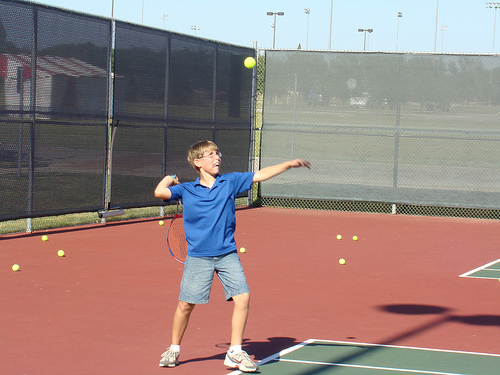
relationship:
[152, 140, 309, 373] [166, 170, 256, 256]
boy wearing blue shirt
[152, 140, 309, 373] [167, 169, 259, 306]
boy wears blue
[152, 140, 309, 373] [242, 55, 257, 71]
boy serving tennis ball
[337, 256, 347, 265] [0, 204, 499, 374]
tennis ball on ground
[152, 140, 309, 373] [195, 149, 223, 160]
boy wearing glasses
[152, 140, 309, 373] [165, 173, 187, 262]
boy holding racket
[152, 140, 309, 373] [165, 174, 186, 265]
boy preparing to swing racket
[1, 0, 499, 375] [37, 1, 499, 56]
blue skies over tennis court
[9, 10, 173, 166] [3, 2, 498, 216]
screen on fence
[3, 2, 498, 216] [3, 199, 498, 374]
fence surrounding tennis court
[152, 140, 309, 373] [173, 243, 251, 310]
boy wearing blue shorts